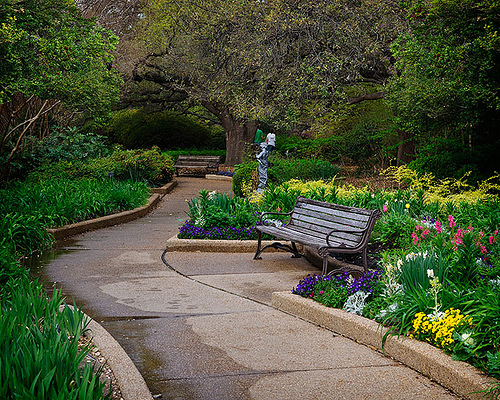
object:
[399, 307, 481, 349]
flowers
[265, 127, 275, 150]
person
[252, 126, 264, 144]
green shirt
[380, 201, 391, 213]
flower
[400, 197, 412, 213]
flower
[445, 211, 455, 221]
flower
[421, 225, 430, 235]
flower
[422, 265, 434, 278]
flower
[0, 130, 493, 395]
grass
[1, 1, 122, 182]
tree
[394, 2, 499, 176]
tree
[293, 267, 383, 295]
purple flowers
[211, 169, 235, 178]
purple flowers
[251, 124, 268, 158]
people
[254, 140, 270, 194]
statue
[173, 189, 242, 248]
flowers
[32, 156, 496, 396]
path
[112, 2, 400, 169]
tree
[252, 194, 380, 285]
bench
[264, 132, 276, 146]
shirt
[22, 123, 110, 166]
bush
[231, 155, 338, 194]
bush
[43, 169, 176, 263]
pavement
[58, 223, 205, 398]
ground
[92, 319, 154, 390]
edge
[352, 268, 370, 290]
purple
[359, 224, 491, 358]
garden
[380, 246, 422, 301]
flowers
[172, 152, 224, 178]
bench